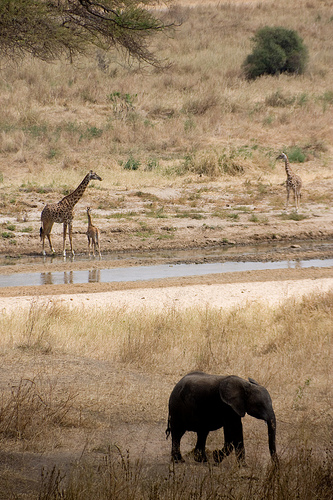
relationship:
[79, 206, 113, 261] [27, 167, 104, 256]
young giraffe by large giraffe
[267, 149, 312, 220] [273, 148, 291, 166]
giraffe has head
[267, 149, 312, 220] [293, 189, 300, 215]
giraffe has front legs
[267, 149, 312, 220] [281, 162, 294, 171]
giraffe has neck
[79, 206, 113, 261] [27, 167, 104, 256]
young giraffe next to large giraffe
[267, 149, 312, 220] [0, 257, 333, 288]
giraffe standing in ripples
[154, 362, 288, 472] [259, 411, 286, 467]
elephant has trunk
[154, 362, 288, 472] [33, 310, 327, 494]
elephant in grass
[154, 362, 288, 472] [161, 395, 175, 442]
elephant has tail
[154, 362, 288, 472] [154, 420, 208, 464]
elephant has back legs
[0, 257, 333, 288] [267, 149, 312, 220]
ripples near giraffe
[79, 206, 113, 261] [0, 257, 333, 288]
young giraffe by ripples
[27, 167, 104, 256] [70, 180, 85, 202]
large giraffe has neck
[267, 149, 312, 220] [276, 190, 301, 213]
giraffe has front legs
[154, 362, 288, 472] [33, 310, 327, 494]
elephant on grass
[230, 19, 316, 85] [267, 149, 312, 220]
bush behind giraffe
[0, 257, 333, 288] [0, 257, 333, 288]
ripples in ripples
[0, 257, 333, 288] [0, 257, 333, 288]
ripples are in ripples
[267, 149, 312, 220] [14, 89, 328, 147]
giraffe in vegetation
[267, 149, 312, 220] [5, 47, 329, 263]
giraffe in field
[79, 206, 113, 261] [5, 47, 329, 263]
young giraffe in field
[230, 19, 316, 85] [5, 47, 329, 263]
bush in field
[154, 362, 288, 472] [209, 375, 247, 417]
elephant has ear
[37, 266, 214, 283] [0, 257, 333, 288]
ripples on ripples